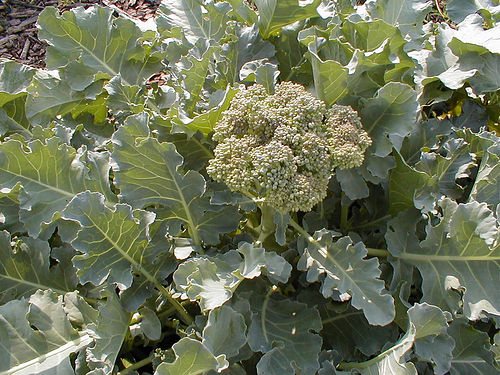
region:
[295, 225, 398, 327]
Large green leaf next to large green leaf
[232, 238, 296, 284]
Large green leaf next to large green leaf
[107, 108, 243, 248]
Large green leaf next to large green leaf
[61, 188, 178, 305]
Large green leaf next to large green leaf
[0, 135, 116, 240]
Large green leaf next to large green leaf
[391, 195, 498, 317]
Large green leaf next to large green leaf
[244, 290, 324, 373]
Large green leaf next to large green leaf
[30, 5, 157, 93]
Large green leaf next to large green leaf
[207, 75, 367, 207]
Large bulb plant next to green leaf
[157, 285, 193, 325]
Green stem on green leaf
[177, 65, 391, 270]
the broccoli is sprouting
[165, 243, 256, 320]
the sun is on the leaves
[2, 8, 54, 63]
sticks on the side of the leaves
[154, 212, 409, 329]
the leaves are wrinkled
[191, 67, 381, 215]
the broccoli is full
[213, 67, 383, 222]
the broccoli is lime green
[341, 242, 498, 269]
the stem is thick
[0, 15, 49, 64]
the sticks are brown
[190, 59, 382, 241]
the broccoli is strong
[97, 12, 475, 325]
the leaves are surrounding the broccoli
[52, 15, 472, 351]
A cauliflower plant is surrounded by leaves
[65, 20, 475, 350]
Cauliflower plant is growing amongst leaves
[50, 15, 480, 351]
Cauliflower surrounded by large leaves and bushes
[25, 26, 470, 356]
Cauliflower is growing in the middle of leaves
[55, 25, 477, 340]
Cauliflower plant growing out of soil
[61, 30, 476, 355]
Cauliflower surrounded a bunch of large leaves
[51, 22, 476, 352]
A white plant growing in the sunlight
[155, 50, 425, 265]
A white plant growing in the middle of green leaves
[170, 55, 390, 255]
Large leaves growing around cauliflower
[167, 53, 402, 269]
Large cauliflower vegetable growing in sunlight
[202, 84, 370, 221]
a bunch of brocolli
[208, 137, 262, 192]
piece of brocolli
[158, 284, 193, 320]
stem of a leaf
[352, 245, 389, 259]
stem of a leaf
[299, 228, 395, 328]
a leaf in shade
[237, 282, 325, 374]
a leaf in shade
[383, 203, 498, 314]
a leaf in shade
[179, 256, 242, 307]
a leaf in the light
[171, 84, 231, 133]
a leaf in the light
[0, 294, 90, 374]
a leaf in the light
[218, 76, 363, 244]
brocolli is growing on a tree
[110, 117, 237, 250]
a green leaf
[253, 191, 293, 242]
stalk of brocolli on a bush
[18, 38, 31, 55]
a piece of wood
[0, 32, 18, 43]
a piece of wood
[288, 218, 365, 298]
the stem of a leaf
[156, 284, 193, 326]
the stem of a leaf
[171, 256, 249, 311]
a leaf in bright light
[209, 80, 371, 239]
head of brocolli